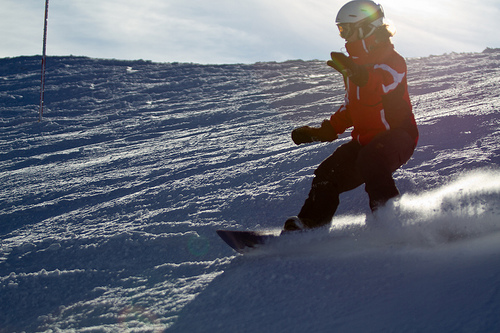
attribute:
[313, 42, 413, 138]
jacket — red, white 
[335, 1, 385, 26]
helmet — SILVER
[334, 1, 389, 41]
helmet — gray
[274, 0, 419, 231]
person — snow boarding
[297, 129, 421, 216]
pants — black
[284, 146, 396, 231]
pants — black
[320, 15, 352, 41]
lenses — big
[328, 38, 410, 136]
jacket — wine red, white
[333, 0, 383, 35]
helmet — gray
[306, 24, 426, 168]
jacket — RED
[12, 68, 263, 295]
hill — SNOW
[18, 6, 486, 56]
sky — light blue, cloudy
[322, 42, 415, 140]
jacket — white, red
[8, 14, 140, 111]
pole — large, gray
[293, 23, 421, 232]
uniform — red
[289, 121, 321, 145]
glove — wine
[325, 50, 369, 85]
glove — wine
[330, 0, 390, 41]
helmet — white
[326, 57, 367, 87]
hand — extended